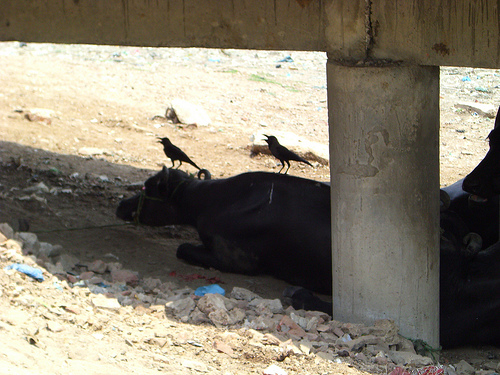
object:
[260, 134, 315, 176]
bird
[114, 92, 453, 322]
cow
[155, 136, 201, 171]
bird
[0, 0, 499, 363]
bridge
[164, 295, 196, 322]
rock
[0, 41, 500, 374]
ground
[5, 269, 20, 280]
rock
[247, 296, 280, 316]
rock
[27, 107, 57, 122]
rock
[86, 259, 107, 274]
rock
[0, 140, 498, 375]
shade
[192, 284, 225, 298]
trash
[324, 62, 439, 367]
column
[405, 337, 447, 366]
plant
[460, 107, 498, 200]
cow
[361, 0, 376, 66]
crack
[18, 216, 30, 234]
stake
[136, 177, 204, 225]
harness